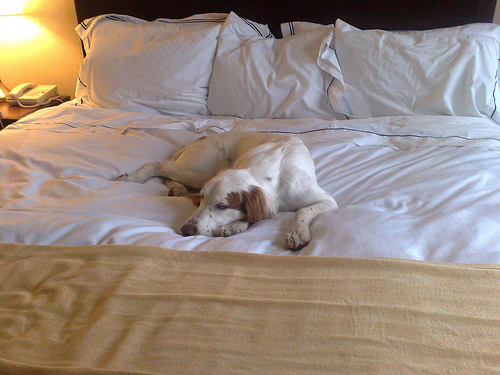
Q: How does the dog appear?
A: Sleepy.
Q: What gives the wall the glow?
A: Lamp.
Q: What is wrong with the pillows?
A: Wrinkled.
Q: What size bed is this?
A: King.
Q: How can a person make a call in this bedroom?
A: Use the phone.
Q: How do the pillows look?
A: Fluffy.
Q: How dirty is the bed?
A: It is clean.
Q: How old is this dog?
A: Senior.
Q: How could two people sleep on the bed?
A: Move the dog.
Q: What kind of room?
A: A bedroom.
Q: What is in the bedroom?
A: A bed.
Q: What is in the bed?
A: A dog.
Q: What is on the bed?
A: Sheets.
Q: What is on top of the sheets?
A: A blanket.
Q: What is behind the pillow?
A: A headboard.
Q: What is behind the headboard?
A: A wall.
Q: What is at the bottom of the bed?
A: A blanket.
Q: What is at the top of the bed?
A: Pillows.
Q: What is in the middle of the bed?
A: Dog.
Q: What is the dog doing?
A: Sleeping.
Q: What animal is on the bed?
A: Dog.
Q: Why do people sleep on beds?
A: Comfort.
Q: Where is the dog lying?
A: On the bed.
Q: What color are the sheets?
A: White.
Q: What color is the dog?
A: White.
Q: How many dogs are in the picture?
A: One.